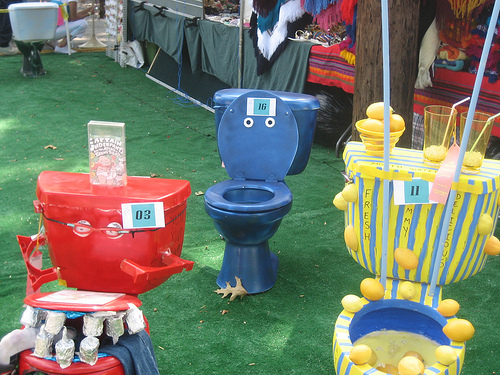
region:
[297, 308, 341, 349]
par tof a floor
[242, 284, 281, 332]
pat of a line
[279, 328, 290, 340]
part of a floor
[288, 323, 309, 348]
par of a line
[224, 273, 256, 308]
pasrt of a base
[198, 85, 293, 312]
the toilet is blue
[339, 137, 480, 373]
toilet has lemon designs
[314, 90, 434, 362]
toilet has lemon designs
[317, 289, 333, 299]
part of a surface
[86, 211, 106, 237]
part of a tank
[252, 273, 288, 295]
side of a tank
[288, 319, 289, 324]
edge of a leaf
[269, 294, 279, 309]
side of a tank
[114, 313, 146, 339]
part of a towel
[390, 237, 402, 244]
part of a board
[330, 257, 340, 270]
edge of a field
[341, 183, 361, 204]
lemon on a toliet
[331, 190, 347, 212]
lemon on a toliet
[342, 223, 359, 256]
lemon on a toliet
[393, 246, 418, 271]
lemon on a toliet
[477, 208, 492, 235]
lemon on a toliet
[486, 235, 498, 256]
lemon on a toliet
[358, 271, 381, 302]
lemon on a toliet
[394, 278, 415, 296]
lemon on a toliet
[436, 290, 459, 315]
lemon on a toliet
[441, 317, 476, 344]
lemon on a toliet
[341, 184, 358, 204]
lemon on a toilet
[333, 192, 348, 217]
lemon on a toilet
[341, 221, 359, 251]
lemon on a toilet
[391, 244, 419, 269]
lemon on a toilet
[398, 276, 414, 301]
lemon on a toilet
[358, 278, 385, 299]
lemon on a toilet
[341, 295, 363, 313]
lemon on a toilet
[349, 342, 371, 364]
lemon on a toilet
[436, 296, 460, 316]
lemon on a toilet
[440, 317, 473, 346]
lemon on a toilet